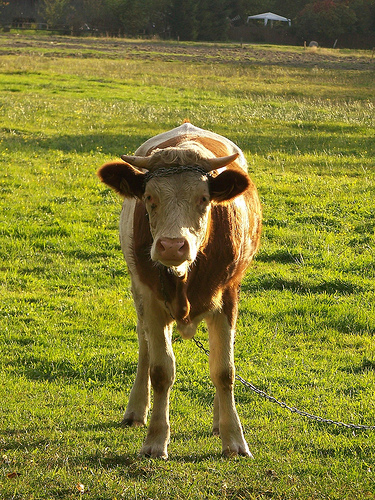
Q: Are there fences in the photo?
A: No, there are no fences.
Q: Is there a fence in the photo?
A: No, there are no fences.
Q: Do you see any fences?
A: No, there are no fences.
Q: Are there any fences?
A: No, there are no fences.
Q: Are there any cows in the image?
A: Yes, there is a cow.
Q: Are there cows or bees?
A: Yes, there is a cow.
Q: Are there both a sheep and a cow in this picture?
A: No, there is a cow but no sheep.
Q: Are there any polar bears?
A: No, there are no polar bears.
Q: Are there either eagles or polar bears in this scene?
A: No, there are no polar bears or eagles.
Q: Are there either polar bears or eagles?
A: No, there are no polar bears or eagles.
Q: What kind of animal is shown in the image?
A: The animal is a cow.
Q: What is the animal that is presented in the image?
A: The animal is a cow.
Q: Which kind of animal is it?
A: The animal is a cow.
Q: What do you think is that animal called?
A: That is a cow.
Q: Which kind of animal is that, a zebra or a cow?
A: That is a cow.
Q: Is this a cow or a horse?
A: This is a cow.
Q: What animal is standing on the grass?
A: The cow is standing on the grass.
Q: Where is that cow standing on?
A: The cow is standing on the grass.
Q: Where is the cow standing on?
A: The cow is standing on the grass.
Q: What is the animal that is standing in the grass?
A: The animal is a cow.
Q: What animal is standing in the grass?
A: The animal is a cow.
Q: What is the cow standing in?
A: The cow is standing in the grass.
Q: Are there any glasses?
A: No, there are no glasses.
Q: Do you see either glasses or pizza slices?
A: No, there are no glasses or pizza slices.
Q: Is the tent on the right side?
A: Yes, the tent is on the right of the image.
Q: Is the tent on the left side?
A: No, the tent is on the right of the image.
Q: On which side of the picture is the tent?
A: The tent is on the right of the image.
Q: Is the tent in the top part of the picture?
A: Yes, the tent is in the top of the image.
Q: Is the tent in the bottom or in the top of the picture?
A: The tent is in the top of the image.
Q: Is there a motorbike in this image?
A: No, there are no motorcycles.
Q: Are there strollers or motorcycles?
A: No, there are no motorcycles or strollers.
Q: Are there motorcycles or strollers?
A: No, there are no motorcycles or strollers.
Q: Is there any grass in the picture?
A: Yes, there is grass.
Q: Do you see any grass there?
A: Yes, there is grass.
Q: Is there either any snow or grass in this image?
A: Yes, there is grass.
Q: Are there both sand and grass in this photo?
A: No, there is grass but no sand.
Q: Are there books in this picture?
A: No, there are no books.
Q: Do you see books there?
A: No, there are no books.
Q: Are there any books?
A: No, there are no books.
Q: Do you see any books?
A: No, there are no books.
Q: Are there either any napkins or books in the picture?
A: No, there are no books or napkins.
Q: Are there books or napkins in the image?
A: No, there are no books or napkins.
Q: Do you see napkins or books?
A: No, there are no books or napkins.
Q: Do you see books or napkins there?
A: No, there are no books or napkins.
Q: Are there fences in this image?
A: No, there are no fences.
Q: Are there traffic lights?
A: No, there are no traffic lights.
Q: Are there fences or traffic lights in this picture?
A: No, there are no traffic lights or fences.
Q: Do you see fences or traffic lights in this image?
A: No, there are no traffic lights or fences.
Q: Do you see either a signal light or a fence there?
A: No, there are no traffic lights or fences.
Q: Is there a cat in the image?
A: No, there are no cats.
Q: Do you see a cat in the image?
A: No, there are no cats.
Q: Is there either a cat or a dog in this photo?
A: No, there are no cats or dogs.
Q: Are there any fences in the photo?
A: No, there are no fences.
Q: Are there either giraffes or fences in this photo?
A: No, there are no fences or giraffes.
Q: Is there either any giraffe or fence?
A: No, there are no fences or giraffes.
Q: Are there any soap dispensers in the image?
A: No, there are no soap dispensers.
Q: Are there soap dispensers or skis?
A: No, there are no soap dispensers or skis.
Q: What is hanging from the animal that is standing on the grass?
A: The chain is hanging from the cow.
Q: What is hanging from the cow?
A: The chain is hanging from the cow.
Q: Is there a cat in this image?
A: No, there are no cats.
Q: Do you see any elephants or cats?
A: No, there are no cats or elephants.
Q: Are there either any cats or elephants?
A: No, there are no cats or elephants.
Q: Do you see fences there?
A: No, there are no fences.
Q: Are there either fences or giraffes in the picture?
A: No, there are no fences or giraffes.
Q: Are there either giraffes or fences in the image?
A: No, there are no fences or giraffes.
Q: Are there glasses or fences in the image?
A: No, there are no fences or glasses.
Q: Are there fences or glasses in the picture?
A: No, there are no fences or glasses.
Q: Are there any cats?
A: No, there are no cats.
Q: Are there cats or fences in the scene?
A: No, there are no cats or fences.